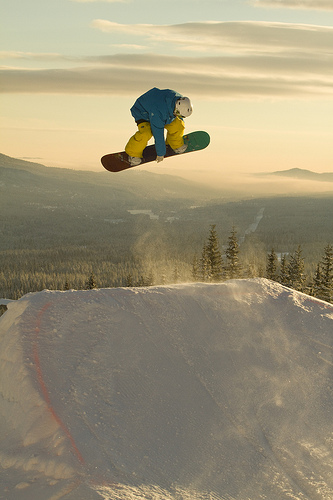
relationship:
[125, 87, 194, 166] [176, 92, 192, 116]
boy has helmet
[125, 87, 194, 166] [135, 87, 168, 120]
boy has coat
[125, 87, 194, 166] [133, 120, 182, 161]
boy has pants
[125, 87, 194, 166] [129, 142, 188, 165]
boy has shoes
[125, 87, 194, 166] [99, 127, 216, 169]
boy holding board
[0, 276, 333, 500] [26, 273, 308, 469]
snow on ramp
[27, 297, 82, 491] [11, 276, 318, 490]
line painted on ramp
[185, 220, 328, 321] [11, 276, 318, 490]
trees behind ramp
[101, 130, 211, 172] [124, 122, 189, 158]
board wearing pants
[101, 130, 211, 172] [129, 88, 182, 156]
board wearing coat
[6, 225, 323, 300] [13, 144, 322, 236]
valley below mountains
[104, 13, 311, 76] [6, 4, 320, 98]
clouds in sky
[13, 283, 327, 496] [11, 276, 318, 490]
snow formed on ramp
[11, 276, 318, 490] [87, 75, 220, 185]
ramp for snowboarders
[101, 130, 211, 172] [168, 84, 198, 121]
board wearing helmet